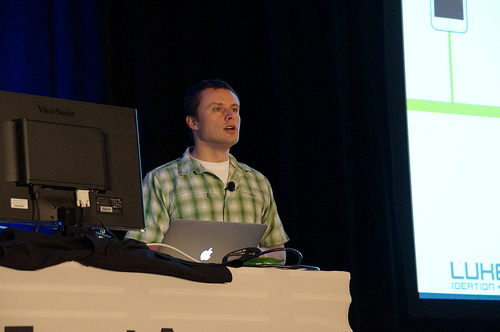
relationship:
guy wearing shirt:
[125, 79, 290, 265] [121, 144, 292, 249]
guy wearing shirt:
[125, 79, 290, 265] [180, 145, 242, 190]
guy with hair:
[139, 77, 311, 260] [182, 68, 240, 119]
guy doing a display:
[125, 79, 290, 265] [401, 0, 500, 300]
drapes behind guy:
[1, 1, 118, 103] [125, 79, 290, 265]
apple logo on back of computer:
[202, 241, 213, 266] [155, 219, 268, 264]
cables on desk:
[220, 240, 323, 273] [0, 266, 352, 332]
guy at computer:
[125, 79, 290, 265] [330, 2, 497, 329]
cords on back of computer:
[58, 198, 315, 270] [159, 215, 269, 264]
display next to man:
[401, 0, 500, 300] [120, 69, 294, 250]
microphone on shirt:
[228, 181, 235, 191] [133, 146, 300, 246]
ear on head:
[180, 106, 200, 130] [181, 80, 241, 148]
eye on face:
[212, 103, 219, 115] [178, 80, 245, 147]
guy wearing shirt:
[125, 79, 290, 265] [140, 147, 288, 265]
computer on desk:
[155, 219, 268, 264] [0, 255, 367, 330]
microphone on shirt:
[224, 180, 235, 192] [124, 151, 289, 262]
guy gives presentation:
[125, 79, 290, 265] [124, 1, 498, 315]